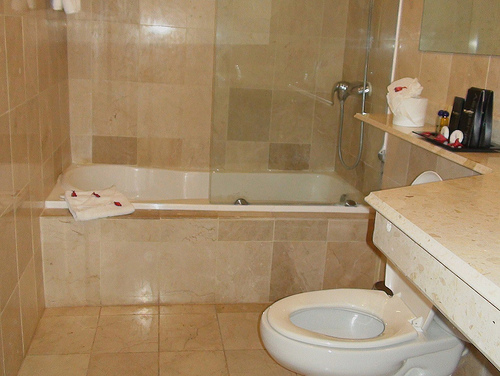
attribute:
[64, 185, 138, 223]
towel — folded, white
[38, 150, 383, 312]
tub — white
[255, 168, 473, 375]
toilet — white, plastic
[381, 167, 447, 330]
lid — up, open, white, plastic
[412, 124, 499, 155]
tray — black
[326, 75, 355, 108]
shower head — handheld, silver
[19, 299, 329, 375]
tile — beige, light brown, tan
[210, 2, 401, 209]
shower door — glass, clear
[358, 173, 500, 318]
countertop — beige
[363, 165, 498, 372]
counter — long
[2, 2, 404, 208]
tile — brown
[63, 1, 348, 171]
tiles — tan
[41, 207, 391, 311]
exterior of the tub — tan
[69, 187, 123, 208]
adornments — red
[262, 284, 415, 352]
seat — oval, white, plastic